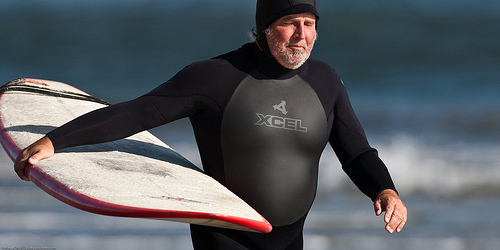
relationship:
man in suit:
[205, 4, 398, 248] [235, 87, 319, 192]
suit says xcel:
[235, 87, 319, 192] [262, 114, 304, 135]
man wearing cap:
[205, 4, 398, 248] [266, 3, 314, 14]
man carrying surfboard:
[205, 4, 398, 248] [6, 76, 220, 223]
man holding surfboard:
[205, 4, 398, 248] [6, 76, 220, 223]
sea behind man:
[380, 34, 429, 85] [205, 4, 398, 248]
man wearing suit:
[205, 4, 398, 248] [235, 87, 319, 192]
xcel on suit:
[262, 114, 304, 135] [235, 87, 319, 192]